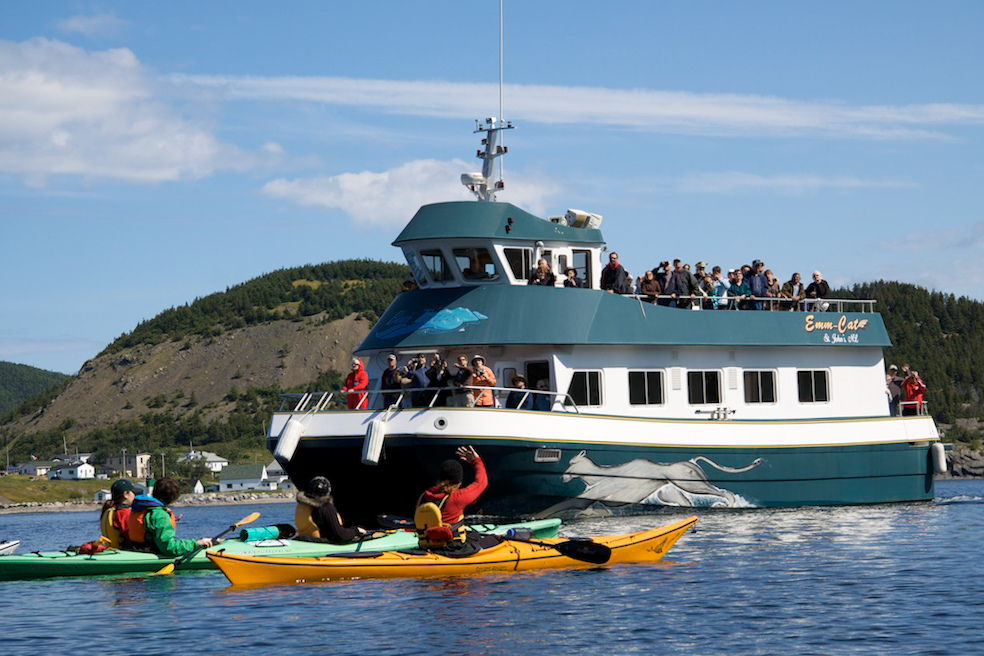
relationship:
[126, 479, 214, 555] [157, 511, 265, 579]
woman has oar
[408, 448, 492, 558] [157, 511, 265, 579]
man has oar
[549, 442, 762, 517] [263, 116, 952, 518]
animal on ship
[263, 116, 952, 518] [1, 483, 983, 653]
ship in water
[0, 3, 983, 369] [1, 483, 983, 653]
sky over water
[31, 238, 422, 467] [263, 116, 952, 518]
hill behind ship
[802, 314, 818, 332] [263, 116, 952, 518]
letter on ship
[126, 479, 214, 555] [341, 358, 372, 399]
woman in red coat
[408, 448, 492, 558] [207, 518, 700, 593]
man in kayak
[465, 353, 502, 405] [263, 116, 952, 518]
person on ship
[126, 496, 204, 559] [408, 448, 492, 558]
jacket on man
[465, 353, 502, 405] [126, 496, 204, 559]
person has a jacket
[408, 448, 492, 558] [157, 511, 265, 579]
man has an oar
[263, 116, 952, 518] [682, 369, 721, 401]
ship has a window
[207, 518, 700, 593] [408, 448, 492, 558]
kayak with a man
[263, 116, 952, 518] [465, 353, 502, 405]
ship with a person